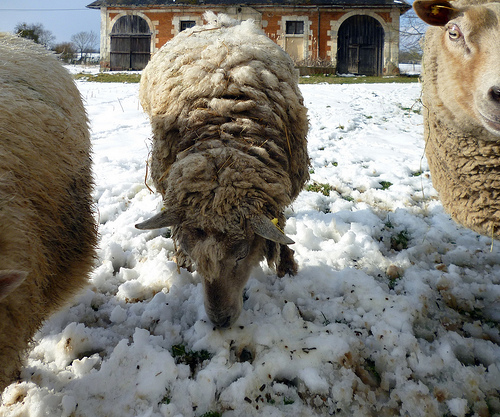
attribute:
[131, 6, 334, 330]
sheep — eating, fuzzy, dirty, beige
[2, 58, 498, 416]
snow — dirty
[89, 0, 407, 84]
building — stone, red, brick, brown, orange, old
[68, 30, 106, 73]
tree — leafless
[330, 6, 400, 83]
doorway — arched, wooden, wood, brown, black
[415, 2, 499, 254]
sheep — looking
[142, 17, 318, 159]
back — wool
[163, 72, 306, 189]
fur — matted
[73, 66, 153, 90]
grass — green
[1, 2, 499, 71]
sky — blue